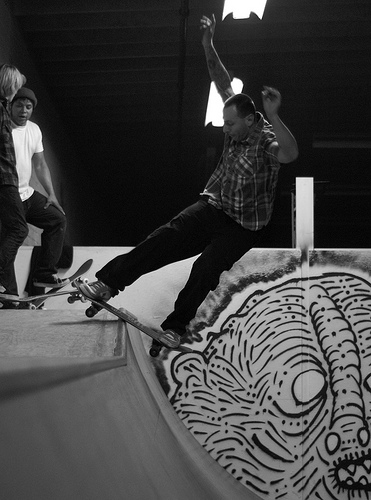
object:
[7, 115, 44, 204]
shirt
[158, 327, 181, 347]
shoe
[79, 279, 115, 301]
shoe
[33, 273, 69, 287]
shoe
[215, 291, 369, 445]
drawing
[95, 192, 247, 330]
jeans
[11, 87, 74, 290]
boy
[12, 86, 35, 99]
beanie hat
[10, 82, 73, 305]
guys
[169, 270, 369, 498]
drawing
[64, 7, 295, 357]
skater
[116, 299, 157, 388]
edge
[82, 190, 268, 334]
pants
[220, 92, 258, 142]
mans head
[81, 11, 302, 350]
guy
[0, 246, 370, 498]
rink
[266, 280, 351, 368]
graffiti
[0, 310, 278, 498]
skate ramp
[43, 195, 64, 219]
man`s hand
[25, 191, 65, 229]
thigh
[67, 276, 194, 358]
skateboard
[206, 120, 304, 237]
shirt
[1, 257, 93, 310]
skateboard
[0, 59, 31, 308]
man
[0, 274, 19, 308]
shoes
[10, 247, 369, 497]
wall